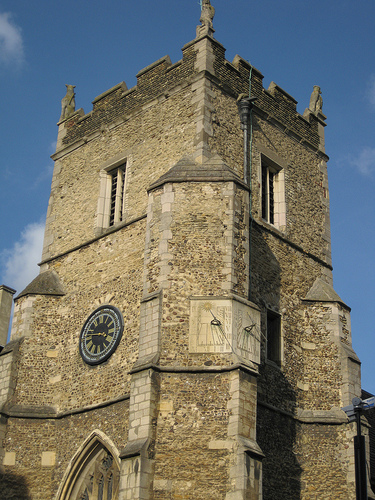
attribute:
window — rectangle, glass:
[95, 159, 132, 238]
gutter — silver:
[231, 60, 260, 197]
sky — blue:
[2, 1, 373, 264]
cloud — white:
[2, 8, 30, 76]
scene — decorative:
[194, 285, 261, 360]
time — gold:
[82, 331, 114, 342]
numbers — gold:
[96, 315, 114, 324]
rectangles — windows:
[99, 147, 309, 235]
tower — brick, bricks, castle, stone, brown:
[7, 0, 353, 492]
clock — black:
[78, 306, 126, 365]